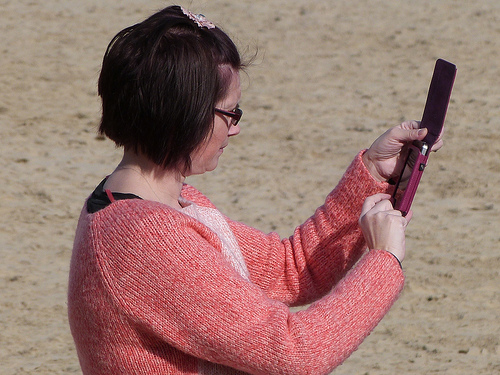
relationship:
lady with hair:
[61, 2, 447, 374] [96, 3, 216, 178]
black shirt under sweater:
[79, 179, 148, 213] [62, 147, 414, 373]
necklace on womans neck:
[111, 158, 173, 205] [117, 148, 191, 198]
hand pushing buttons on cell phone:
[354, 194, 411, 261] [391, 58, 457, 216]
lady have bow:
[61, 2, 447, 374] [179, 5, 221, 31]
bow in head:
[179, 5, 221, 31] [93, 7, 243, 173]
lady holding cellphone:
[61, 2, 447, 374] [389, 43, 465, 215]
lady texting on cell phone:
[61, 2, 447, 374] [385, 53, 458, 218]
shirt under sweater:
[187, 199, 259, 276] [71, 156, 401, 371]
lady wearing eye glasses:
[61, 2, 447, 374] [206, 100, 245, 127]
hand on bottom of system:
[357, 193, 407, 261] [381, 144, 425, 216]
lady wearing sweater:
[61, 2, 447, 374] [62, 147, 414, 373]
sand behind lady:
[2, 1, 499, 372] [61, 2, 447, 374]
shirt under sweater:
[91, 184, 126, 206] [63, 217, 350, 366]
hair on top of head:
[88, 22, 240, 179] [72, 20, 297, 197]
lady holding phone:
[61, 2, 447, 374] [358, 36, 485, 235]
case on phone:
[374, 162, 431, 226] [382, 54, 459, 217]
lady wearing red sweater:
[61, 2, 447, 374] [54, 158, 411, 373]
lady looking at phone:
[61, 2, 447, 374] [369, 51, 458, 226]